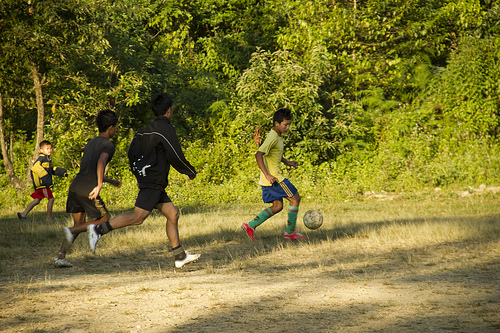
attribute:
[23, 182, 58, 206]
sport shorts — red 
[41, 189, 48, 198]
strips — whites 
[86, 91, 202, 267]
boy — running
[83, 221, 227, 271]
shoes — white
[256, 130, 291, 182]
t-shirt — yellow 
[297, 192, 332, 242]
ball — soccer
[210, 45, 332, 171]
shrub — green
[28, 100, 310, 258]
boys — playing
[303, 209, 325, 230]
ball — soccer 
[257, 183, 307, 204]
shorts — blue , with yellow stripes down the side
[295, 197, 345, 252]
ball — soccer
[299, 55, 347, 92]
leaves — green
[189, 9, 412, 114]
trees — green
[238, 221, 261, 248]
shoe — red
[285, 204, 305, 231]
tube sock — Green 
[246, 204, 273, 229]
tube sock — Green 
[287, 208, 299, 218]
stripe — red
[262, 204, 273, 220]
stripe — red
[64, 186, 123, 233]
shorts — black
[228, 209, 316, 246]
shoes — red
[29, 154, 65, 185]
jacket — black, yellow, sports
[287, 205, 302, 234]
knee sock — bright green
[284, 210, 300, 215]
stripe — red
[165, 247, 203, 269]
tennis shoe — white 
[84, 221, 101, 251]
tennis shoe — white 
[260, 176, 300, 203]
shorts — blue 